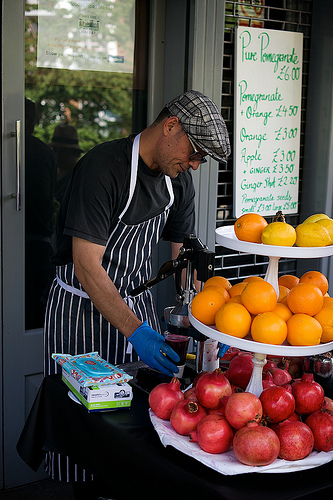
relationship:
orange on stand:
[191, 288, 229, 324] [149, 224, 333, 477]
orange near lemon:
[234, 214, 269, 243] [260, 220, 296, 247]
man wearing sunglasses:
[45, 89, 229, 496] [182, 128, 205, 164]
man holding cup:
[45, 89, 229, 496] [199, 338, 220, 373]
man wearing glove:
[45, 89, 229, 496] [129, 319, 180, 378]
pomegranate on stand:
[149, 377, 183, 420] [149, 224, 333, 477]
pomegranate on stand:
[225, 390, 263, 429] [149, 224, 333, 477]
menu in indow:
[35, 3, 138, 71] [20, 5, 140, 492]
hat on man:
[166, 87, 231, 165] [45, 89, 229, 496]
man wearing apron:
[45, 89, 229, 496] [42, 132, 165, 375]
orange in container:
[191, 288, 229, 324] [151, 224, 329, 476]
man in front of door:
[45, 89, 229, 496] [24, 2, 149, 329]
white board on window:
[236, 25, 303, 217] [210, 3, 301, 273]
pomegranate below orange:
[233, 420, 279, 464] [191, 288, 229, 324]